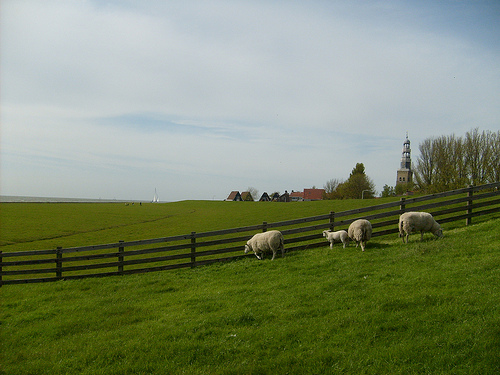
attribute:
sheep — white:
[245, 230, 284, 265]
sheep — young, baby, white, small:
[319, 230, 345, 248]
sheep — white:
[349, 221, 376, 254]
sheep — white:
[396, 212, 443, 245]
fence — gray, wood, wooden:
[0, 182, 499, 289]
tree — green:
[434, 138, 450, 195]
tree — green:
[452, 139, 466, 186]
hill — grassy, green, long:
[0, 187, 499, 374]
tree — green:
[469, 129, 486, 181]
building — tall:
[394, 133, 413, 197]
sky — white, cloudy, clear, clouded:
[0, 0, 488, 201]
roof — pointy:
[303, 189, 330, 201]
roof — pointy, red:
[261, 192, 269, 200]